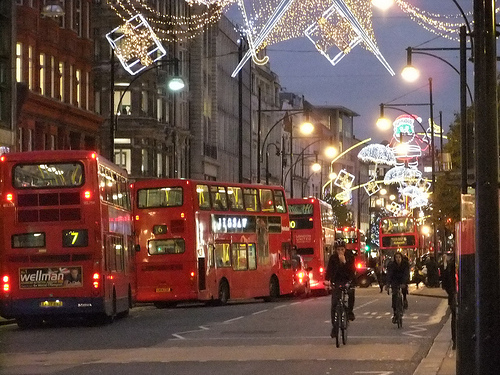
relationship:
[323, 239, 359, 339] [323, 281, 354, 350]
person riding bicycle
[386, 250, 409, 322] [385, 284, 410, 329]
person riding bicycle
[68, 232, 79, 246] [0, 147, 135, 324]
number on bus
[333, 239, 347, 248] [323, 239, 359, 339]
helmet on man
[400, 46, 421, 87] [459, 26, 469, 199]
light hanging from pole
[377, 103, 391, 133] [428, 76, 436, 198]
light hanging from pole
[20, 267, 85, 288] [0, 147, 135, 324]
sign on bus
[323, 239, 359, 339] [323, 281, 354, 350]
person riding on bike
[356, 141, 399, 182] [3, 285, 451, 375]
umbrella above street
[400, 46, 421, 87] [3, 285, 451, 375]
light hanging ove r street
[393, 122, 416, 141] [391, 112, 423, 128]
face with hat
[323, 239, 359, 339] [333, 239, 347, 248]
person wearing a helmet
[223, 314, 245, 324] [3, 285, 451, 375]
line on street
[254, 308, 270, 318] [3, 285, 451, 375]
line on street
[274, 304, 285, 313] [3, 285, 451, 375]
line on street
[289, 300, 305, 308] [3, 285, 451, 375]
line on street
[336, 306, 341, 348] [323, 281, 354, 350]
tire on bicycle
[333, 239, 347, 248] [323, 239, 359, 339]
helmet on person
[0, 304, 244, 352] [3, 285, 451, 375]
shadow in street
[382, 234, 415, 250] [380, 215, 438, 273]
sign on front of bus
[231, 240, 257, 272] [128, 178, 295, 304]
window on bus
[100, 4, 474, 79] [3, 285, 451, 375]
christmas-lights over street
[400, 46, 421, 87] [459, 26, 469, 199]
light on pole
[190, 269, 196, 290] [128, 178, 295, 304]
taillight on bus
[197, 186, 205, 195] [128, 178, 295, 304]
light on inside bus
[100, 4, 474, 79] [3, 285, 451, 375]
christmas-lights above street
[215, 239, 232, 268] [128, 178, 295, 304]
window on bus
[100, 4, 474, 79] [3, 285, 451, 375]
christmas-lights hanging over street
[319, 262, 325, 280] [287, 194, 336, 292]
taillight on back of bus